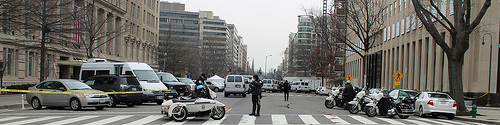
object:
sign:
[342, 74, 353, 83]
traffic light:
[228, 65, 233, 72]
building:
[337, 0, 500, 107]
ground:
[388, 50, 418, 81]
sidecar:
[156, 85, 228, 123]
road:
[0, 79, 496, 125]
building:
[158, 7, 199, 79]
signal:
[227, 66, 233, 72]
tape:
[1, 88, 161, 95]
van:
[78, 62, 167, 110]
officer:
[243, 74, 265, 117]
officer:
[195, 72, 206, 90]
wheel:
[67, 97, 83, 111]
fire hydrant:
[468, 98, 479, 123]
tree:
[7, 2, 81, 82]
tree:
[72, 1, 129, 59]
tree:
[411, 0, 488, 116]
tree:
[327, 0, 384, 88]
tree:
[305, 8, 342, 83]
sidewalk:
[1, 91, 25, 106]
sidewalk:
[462, 105, 497, 122]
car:
[411, 92, 460, 120]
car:
[21, 79, 115, 111]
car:
[156, 91, 229, 123]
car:
[87, 73, 146, 108]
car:
[221, 74, 250, 98]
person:
[281, 79, 291, 101]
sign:
[389, 70, 409, 89]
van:
[222, 74, 247, 98]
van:
[258, 75, 277, 93]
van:
[288, 82, 312, 92]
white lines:
[0, 108, 493, 125]